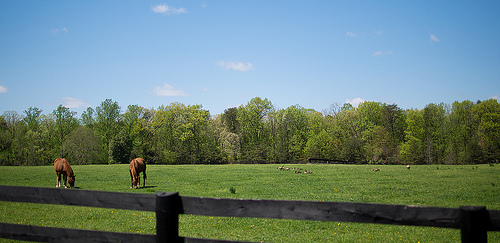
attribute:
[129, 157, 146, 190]
horse — brown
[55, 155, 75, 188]
horse — brown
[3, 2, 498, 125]
sky — blue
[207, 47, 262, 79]
cloud — white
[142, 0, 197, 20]
cloud — white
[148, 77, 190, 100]
cloud — white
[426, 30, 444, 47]
cloud — white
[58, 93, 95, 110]
cloud — white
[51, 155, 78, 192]
horse — brown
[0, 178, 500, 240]
fence — wooden, rail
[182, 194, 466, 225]
slat — wooden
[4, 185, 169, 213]
slat — wooden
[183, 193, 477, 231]
slat — wooden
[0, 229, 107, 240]
slat — wooden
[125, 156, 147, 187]
horse — brown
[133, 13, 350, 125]
clouds — white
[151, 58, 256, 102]
clouds — white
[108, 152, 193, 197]
horse — brown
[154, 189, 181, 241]
fence post — wooden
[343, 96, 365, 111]
cloud — small, wispy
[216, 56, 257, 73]
cloud — small, wispy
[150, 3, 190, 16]
cloud — small, wispy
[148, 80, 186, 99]
cloud — small, wispy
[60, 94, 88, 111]
cloud — small, wispy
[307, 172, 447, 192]
pasture — green, large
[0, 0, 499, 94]
sky — clear, blue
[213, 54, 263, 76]
clouds — puffy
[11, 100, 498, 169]
trees — green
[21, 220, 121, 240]
slat — wooden 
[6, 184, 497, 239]
fence — wooden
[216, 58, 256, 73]
cloud — white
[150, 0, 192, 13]
cloud — white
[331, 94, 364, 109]
cloud — white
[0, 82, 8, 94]
cloud — white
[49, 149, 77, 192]
horse — brown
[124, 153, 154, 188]
horse — brown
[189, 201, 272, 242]
fence — black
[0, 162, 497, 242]
grass — green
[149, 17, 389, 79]
sky — blue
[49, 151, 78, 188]
horse — brown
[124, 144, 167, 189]
horse — brown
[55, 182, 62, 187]
feet — white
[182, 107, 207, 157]
tree — tall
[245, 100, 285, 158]
tree — tall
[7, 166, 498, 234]
pasture — green, grass